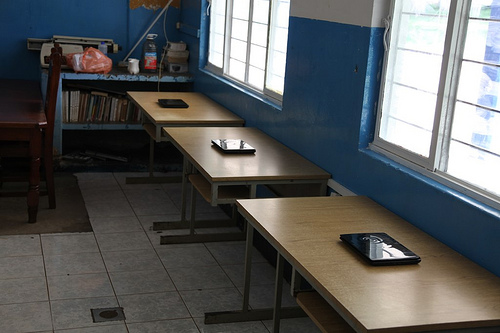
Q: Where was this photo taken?
A: In a classroom.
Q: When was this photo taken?
A: In the daytime.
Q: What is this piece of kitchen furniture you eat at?
A: Table.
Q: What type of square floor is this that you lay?
A: Tile.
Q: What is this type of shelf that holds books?
A: Bookshelf.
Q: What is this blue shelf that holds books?
A: Bookshelf?.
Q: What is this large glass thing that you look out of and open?
A: Window.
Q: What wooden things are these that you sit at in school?
A: Desk.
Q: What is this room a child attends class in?
A: Classroom.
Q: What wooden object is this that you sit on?
A: Chair.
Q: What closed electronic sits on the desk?
A: Laptop.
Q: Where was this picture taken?
A: In a classroom.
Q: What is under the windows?
A: Desk.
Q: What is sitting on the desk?
A: Tablets.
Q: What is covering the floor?
A: Tile.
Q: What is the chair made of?
A: Wood.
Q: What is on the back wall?
A: A bookcase.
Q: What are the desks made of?
A: Wood.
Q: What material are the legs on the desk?
A: Metal.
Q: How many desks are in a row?
A: Three.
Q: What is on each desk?
A: Laptop.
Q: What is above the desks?
A: Windows.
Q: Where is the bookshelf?
A: Back wall.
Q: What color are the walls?
A: Blue and white.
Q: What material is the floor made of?
A: Tile.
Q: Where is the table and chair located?
A: Beside book case.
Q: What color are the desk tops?
A: Brown.